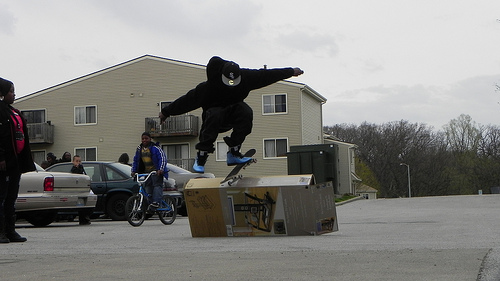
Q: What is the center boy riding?
A: Skateboard.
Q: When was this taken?
A: Day time.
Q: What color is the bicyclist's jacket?
A: Blue.